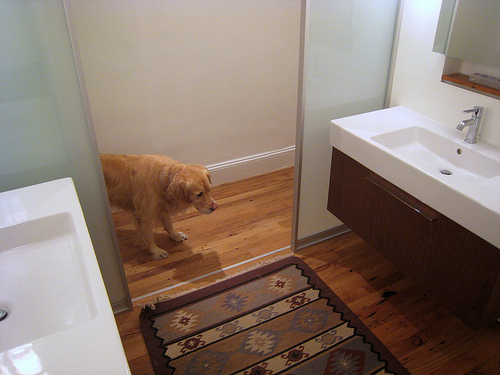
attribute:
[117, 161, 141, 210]
jersey — white, blue, here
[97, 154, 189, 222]
body — here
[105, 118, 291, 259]
dog — standing, looking, brown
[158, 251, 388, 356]
rug — laying, decorated, located, brown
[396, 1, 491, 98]
vanity — square, displaying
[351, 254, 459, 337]
floor — made, hardwood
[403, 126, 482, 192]
sink — white, next, chrome, rectangular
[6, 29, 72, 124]
doori — glass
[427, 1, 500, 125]
light — on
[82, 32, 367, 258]
door — open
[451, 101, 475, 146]
faucet — silver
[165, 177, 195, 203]
ear — floppy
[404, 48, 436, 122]
wall — white, behind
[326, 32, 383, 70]
glass — frosted